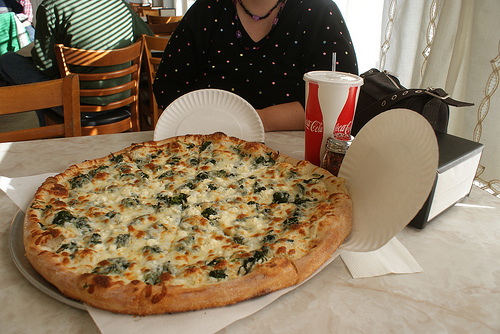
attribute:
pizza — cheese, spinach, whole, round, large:
[21, 130, 355, 318]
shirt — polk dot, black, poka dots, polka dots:
[153, 2, 361, 108]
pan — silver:
[9, 199, 101, 312]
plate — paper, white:
[338, 104, 441, 254]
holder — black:
[408, 137, 486, 233]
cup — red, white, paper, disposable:
[303, 49, 364, 169]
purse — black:
[349, 67, 478, 139]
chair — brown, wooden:
[1, 75, 82, 142]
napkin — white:
[342, 237, 425, 282]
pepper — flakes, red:
[326, 151, 346, 173]